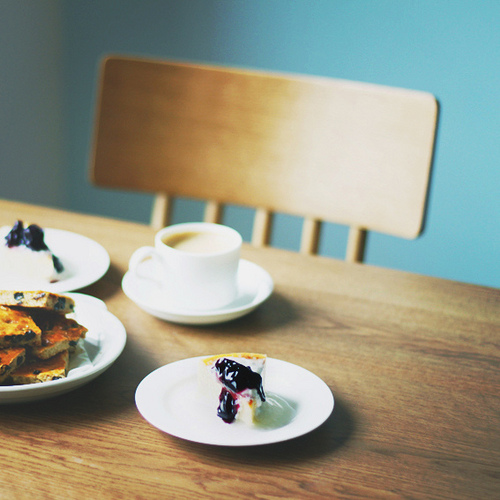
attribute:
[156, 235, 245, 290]
cup — small, white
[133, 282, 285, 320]
saucer — white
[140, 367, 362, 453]
plate — white, porcelain, circular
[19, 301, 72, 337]
cookie — delicious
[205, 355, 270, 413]
cheesecake — blueberry, delicious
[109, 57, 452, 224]
chair — wooden, wood, tan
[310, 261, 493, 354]
table — large, wooden, wood, brown, smooth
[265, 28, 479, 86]
wall — blue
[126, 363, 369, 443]
dish — white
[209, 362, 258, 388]
toppings — blueberry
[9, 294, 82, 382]
squares — chocolate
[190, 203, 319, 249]
slats — wooden